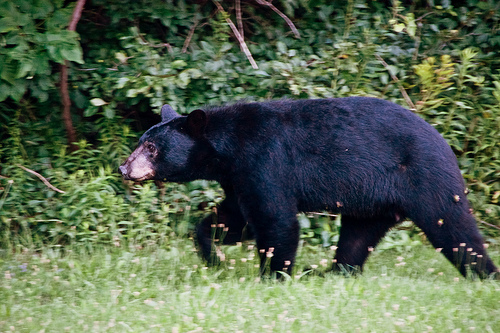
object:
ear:
[158, 101, 185, 125]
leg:
[192, 193, 242, 271]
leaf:
[59, 44, 85, 64]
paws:
[303, 267, 359, 278]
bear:
[117, 93, 497, 281]